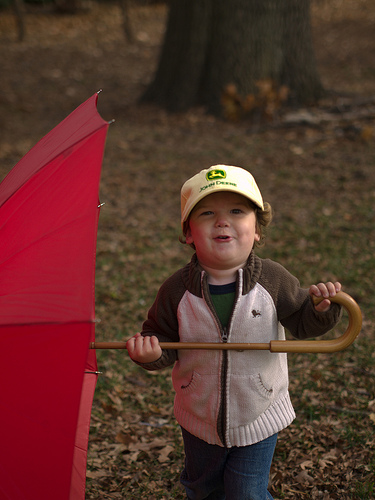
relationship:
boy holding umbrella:
[121, 161, 345, 499] [1, 90, 365, 500]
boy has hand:
[121, 161, 345, 499] [126, 330, 166, 366]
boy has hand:
[121, 161, 345, 499] [306, 278, 344, 317]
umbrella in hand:
[1, 90, 365, 500] [126, 330, 166, 366]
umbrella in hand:
[1, 90, 365, 500] [306, 278, 344, 317]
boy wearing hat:
[121, 161, 345, 499] [176, 162, 264, 239]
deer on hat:
[205, 169, 228, 181] [176, 162, 264, 239]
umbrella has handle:
[1, 90, 365, 500] [89, 284, 363, 357]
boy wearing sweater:
[121, 161, 345, 499] [132, 247, 344, 450]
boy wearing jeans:
[121, 161, 345, 499] [178, 417, 281, 499]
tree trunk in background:
[136, 2, 350, 127] [3, 2, 374, 161]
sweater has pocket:
[132, 247, 344, 450] [236, 375, 274, 428]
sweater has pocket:
[132, 247, 344, 450] [178, 370, 216, 430]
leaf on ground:
[135, 436, 167, 450] [2, 30, 374, 496]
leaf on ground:
[291, 456, 317, 474] [2, 30, 374, 496]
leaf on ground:
[155, 443, 174, 465] [2, 30, 374, 496]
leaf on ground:
[105, 390, 125, 415] [2, 30, 374, 496]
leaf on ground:
[315, 451, 338, 470] [2, 30, 374, 496]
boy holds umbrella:
[121, 161, 345, 499] [1, 90, 365, 500]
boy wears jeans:
[121, 161, 345, 499] [178, 417, 281, 499]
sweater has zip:
[132, 247, 344, 450] [197, 266, 246, 451]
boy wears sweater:
[121, 161, 345, 499] [132, 247, 344, 450]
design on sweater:
[247, 306, 261, 321] [132, 247, 344, 450]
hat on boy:
[176, 162, 264, 239] [121, 161, 345, 499]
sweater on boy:
[132, 247, 344, 450] [121, 161, 345, 499]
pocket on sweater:
[236, 375, 274, 428] [132, 247, 344, 450]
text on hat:
[197, 180, 238, 194] [176, 162, 264, 239]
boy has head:
[121, 161, 345, 499] [178, 165, 264, 271]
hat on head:
[176, 162, 264, 239] [178, 165, 264, 271]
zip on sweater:
[197, 266, 246, 451] [132, 247, 344, 450]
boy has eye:
[121, 161, 345, 499] [229, 207, 244, 217]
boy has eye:
[121, 161, 345, 499] [199, 208, 215, 218]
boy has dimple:
[121, 161, 345, 499] [240, 228, 251, 241]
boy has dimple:
[121, 161, 345, 499] [194, 234, 204, 245]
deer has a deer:
[205, 169, 226, 180] [205, 169, 228, 181]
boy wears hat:
[121, 161, 345, 499] [176, 162, 264, 239]